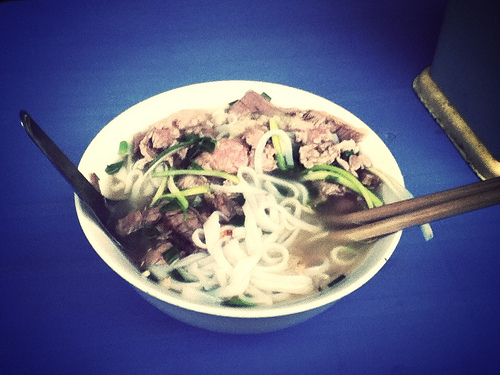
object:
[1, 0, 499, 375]
table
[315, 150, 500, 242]
chopsticks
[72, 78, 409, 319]
bowl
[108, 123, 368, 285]
noodles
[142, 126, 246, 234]
meat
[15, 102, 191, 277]
spoon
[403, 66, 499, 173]
object